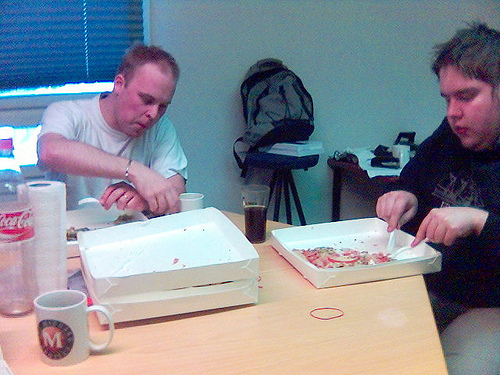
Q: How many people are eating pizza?
A: 2.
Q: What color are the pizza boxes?
A: White.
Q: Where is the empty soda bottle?
A: Behind the pizza boxes.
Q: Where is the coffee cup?
A: Next to the pizza boxes.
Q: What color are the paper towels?
A: White.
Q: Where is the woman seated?
A: There are no women.